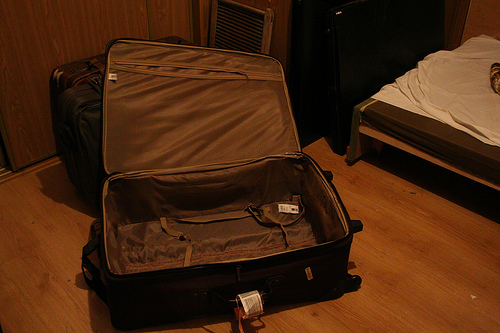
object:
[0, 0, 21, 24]
wood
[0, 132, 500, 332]
floor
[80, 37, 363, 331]
suitcase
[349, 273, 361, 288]
wheel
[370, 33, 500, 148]
sheet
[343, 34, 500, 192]
bed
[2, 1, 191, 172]
wall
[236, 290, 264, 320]
tag